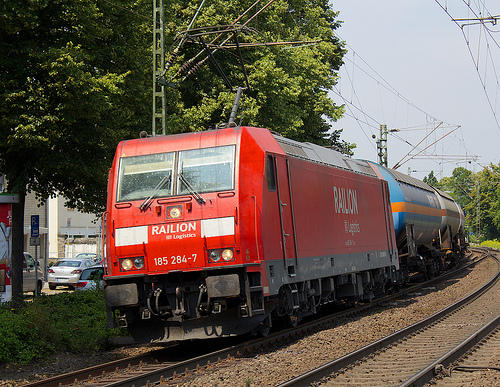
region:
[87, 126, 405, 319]
A red train engine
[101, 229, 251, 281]
Lights are lit on red engine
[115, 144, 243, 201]
Windshield of train engine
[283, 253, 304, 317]
Steps on train engine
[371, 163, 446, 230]
A blue and yellow train car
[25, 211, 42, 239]
A blue sign in a parking lot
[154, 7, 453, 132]
Electricity to the rail cars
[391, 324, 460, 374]
A set of train tracks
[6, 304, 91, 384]
Bushes near the train tracks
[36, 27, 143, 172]
Trees very near the train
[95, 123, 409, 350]
the train is on the tracks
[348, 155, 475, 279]
tank is pulled by train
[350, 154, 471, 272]
tank is on tracks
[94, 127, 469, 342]
train pulls tank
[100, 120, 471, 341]
train in front of tank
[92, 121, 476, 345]
tank behind train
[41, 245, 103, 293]
car is parked off in distance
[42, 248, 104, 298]
car is to left of train in picture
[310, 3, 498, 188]
the sky looks overcast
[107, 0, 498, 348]
train travels under powerlines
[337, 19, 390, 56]
white clouds in blue sky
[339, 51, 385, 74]
white clouds in blue sky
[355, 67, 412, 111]
white clouds in blue sky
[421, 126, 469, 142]
white clouds in blue sky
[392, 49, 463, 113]
white clouds in blue sky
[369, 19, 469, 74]
white clouds in blue sky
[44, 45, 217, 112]
green leaves on trees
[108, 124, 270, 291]
red enginer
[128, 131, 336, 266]
red train on engine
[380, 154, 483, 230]
blue train on engine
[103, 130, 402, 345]
a red train engine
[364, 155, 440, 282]
a blue orange tank car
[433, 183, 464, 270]
a silver tank car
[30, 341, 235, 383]
a set of train tracks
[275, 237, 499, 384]
a white plastic carton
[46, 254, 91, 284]
a parked silver car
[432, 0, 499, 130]
an overhead power line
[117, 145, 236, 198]
a front train windshield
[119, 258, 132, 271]
a train front headlight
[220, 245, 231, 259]
a train front headlight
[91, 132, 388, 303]
red passenger train engine on tracks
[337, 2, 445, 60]
white clouds in blue sky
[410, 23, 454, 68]
white clouds in blue sky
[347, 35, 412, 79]
white clouds in blue sky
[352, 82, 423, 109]
white clouds in blue sky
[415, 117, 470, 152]
white clouds in blue sky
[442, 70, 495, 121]
white clouds in blue sky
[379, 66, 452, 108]
white clouds in blue sky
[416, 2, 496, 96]
white clouds in blue sky